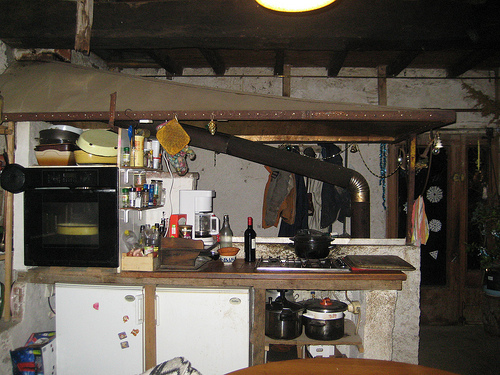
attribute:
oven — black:
[22, 164, 123, 271]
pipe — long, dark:
[104, 117, 374, 240]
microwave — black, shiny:
[23, 177, 117, 268]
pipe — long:
[165, 116, 389, 209]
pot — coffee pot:
[196, 211, 221, 241]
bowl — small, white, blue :
[217, 245, 240, 265]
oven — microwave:
[15, 162, 137, 262]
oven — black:
[14, 142, 151, 270]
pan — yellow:
[57, 213, 107, 245]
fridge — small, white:
[55, 283, 144, 373]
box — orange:
[168, 212, 187, 237]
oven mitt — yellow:
[154, 117, 194, 156]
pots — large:
[268, 282, 346, 344]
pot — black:
[295, 232, 331, 257]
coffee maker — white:
[168, 169, 220, 251]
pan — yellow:
[53, 219, 100, 239]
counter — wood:
[15, 258, 404, 295]